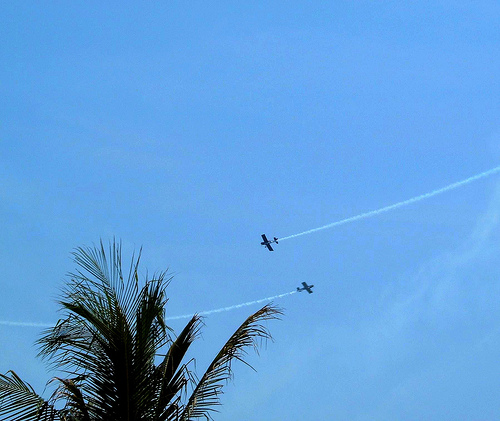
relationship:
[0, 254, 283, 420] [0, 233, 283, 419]
top on tree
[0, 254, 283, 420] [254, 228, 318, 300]
tree below plane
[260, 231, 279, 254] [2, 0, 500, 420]
plane in sky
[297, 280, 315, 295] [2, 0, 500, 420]
plane in sky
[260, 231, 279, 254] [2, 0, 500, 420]
airplane in sky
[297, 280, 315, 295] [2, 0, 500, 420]
airplane in sky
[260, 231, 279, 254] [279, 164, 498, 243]
airplane has white smoke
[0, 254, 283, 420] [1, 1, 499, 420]
palm tree in wind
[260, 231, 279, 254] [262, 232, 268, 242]
plane has a wing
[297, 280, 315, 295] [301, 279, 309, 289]
plane has a wing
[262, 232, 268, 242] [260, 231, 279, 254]
wing on plane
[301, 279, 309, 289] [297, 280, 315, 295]
wing on plane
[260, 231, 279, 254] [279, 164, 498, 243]
plane has white smoke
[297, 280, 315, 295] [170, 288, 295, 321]
plane has white smoke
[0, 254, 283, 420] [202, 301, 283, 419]
green tree has a branch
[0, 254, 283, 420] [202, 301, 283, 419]
coconut tree has a palm fralm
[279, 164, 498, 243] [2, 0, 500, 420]
chem trail in sky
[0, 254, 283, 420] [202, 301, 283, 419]
tree has green palm leaves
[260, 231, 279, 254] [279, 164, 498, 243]
plane has white chemtrails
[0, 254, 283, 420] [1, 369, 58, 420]
coconut tree has green palms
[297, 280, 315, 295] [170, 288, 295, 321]
plane has white chemtrails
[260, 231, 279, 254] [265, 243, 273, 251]
plane has wings